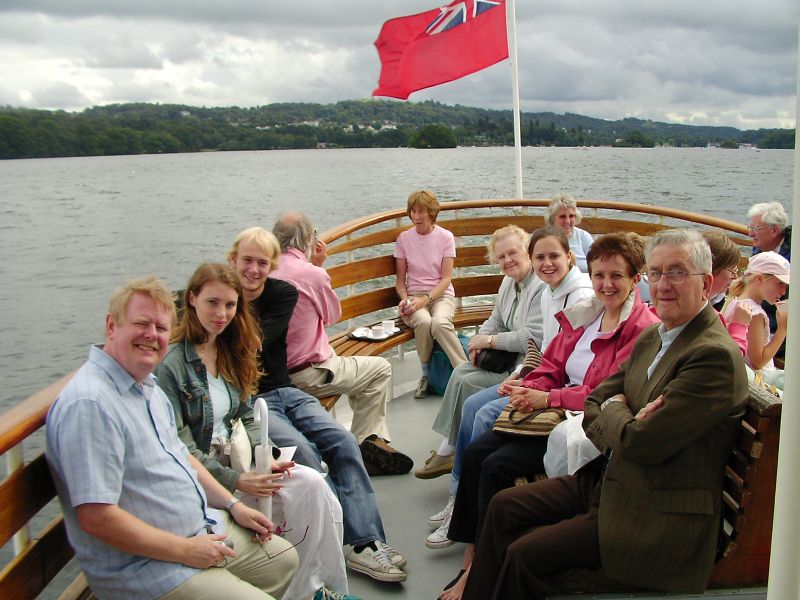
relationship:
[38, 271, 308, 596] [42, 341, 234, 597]
man wearing shirt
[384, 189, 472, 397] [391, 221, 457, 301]
lady wears shirt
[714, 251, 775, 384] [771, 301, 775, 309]
girl slips drink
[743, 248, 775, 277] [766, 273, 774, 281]
cap with visor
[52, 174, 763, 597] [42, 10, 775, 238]
people enjoying outdoors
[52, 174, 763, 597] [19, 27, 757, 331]
people enjoying outdoors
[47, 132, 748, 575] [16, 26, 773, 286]
people enjoying outdoors